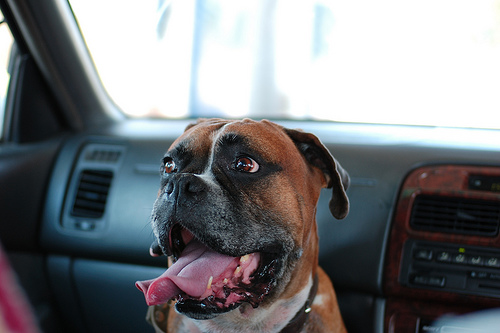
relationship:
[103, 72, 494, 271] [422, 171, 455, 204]
car has wood grain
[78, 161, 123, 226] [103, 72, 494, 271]
vent in car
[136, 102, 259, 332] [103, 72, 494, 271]
dog in car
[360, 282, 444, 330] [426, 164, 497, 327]
car's center console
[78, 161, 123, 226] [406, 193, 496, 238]
vent for vent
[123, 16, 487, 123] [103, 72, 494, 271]
windsheild of car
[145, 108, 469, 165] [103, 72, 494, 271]
dashboard of car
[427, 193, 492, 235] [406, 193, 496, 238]
vent for vent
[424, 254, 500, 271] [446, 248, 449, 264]
climate control buttons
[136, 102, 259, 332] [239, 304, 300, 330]
dog has white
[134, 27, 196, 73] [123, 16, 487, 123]
light on windsheild